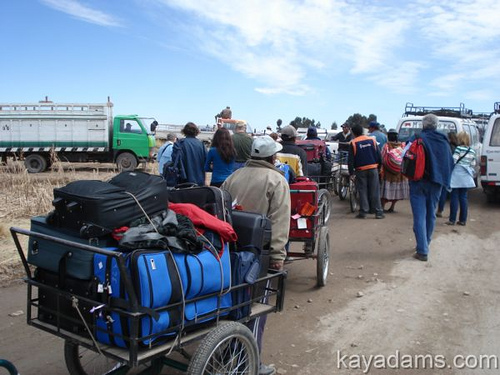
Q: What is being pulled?
A: Suitcases.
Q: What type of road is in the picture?
A: Dirt.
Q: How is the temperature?
A: Cold.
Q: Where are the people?
A: In the road.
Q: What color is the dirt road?
A: Brown.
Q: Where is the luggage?
A: On the cart.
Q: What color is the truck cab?
A: Green.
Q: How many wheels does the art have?
A: Two.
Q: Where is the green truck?
A: In the distance.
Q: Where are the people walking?
A: Behind cars.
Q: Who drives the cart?
A: Men pull the carts.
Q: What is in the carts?
A: Luggage.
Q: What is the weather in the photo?
A: Clear and sunny.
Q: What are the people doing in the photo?
A: Traveling.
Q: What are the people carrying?
A: Luggage.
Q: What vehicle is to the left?
A: A construction vehicle.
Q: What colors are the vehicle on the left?
A: Green and white.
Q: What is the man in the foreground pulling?
A: A cart full of luggage.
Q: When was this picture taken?
A: Maybe the afternoon.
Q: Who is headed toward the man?
A: A crowd.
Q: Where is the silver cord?
A: Tied on cart.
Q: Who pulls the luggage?
A: A man.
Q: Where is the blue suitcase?
A: On cart.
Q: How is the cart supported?
A: A wheel.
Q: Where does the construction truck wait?
A: Side of road.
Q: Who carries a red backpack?
A: Man in blue shirt.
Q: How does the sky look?
A: Blue and a little cloudy.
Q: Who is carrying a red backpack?
A: The tall man with the blue jacket.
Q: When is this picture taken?
A: In the daytime.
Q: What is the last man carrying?
A: A little wagon with suitcases.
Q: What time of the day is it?
A: Looks like the afternoon time.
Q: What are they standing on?
A: Dirt.